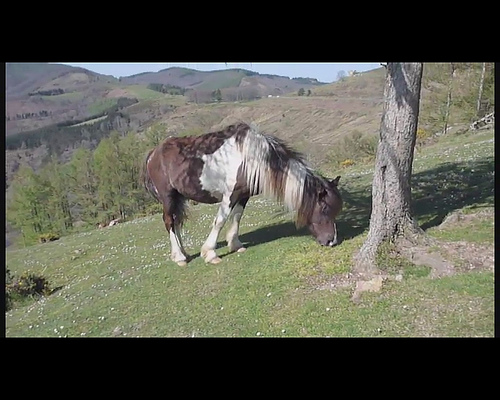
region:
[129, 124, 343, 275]
a brown and white horse grazing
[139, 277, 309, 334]
short green grass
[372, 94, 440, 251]
a gray tree trunk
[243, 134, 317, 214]
brown and white horse mane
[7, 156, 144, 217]
trees on the hillside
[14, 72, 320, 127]
rolling hills in the countryside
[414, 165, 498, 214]
the shadow of a tree on the ground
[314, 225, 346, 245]
the horse's nose to the ground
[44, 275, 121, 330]
tiny white flowers in the grass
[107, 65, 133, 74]
hazy blue sky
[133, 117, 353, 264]
A black and white horse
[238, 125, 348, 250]
The horse has a long mane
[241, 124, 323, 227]
The horses mane is striped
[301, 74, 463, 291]
A tree on the hill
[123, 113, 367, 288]
The horse is standing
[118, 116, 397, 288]
The horse is on a hill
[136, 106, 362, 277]
The horse is eating grass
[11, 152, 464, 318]
The hill has small white flowers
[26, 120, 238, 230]
A cluster of trees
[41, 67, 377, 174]
Brown and green hills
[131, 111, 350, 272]
a pony next to a tree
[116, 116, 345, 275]
white and brown pony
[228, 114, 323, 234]
mane is brown and white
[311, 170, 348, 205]
ears of pony tail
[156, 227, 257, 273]
end of legs are white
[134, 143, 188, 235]
tail of horse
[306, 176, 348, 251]
face of pony is brown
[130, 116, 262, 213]
white and brown pony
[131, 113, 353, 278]
pony eats green grass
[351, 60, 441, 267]
trunk of tree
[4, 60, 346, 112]
Mountains are in the distance.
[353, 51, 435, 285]
A tree trunk.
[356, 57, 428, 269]
The tree trunk is gray.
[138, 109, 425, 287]
A horse is by the tree.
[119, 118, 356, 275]
The horse is brown and white.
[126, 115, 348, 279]
The horse is eating grass.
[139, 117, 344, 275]
The horse has a long mane.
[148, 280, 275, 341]
The grass is short.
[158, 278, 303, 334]
The grass is green.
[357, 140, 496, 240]
The tree's shadow is on the ground.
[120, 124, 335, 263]
brown and white horse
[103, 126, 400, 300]
horse is grazing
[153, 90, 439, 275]
horse is near tree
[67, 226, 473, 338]
horse is on hill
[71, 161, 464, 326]
land near tree is green and barren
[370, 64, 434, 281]
tree has brown trunk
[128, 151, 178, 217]
horse has brown tail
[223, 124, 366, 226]
horse has white and brown mane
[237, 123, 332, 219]
horse has long and thin mane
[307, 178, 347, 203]
horse has brown ears